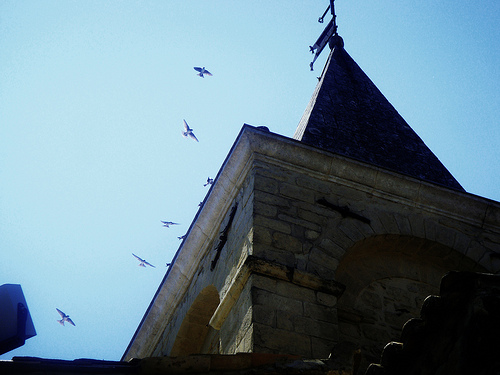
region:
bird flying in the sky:
[50, 304, 82, 334]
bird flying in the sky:
[129, 245, 161, 275]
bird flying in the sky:
[154, 213, 186, 230]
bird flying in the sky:
[175, 117, 204, 147]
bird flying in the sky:
[191, 58, 216, 83]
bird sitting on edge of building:
[204, 171, 221, 192]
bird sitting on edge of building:
[194, 200, 206, 208]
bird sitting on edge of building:
[176, 233, 189, 243]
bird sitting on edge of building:
[163, 261, 178, 268]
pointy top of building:
[141, 11, 481, 360]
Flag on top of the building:
[307, 2, 359, 79]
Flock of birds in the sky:
[54, 64, 220, 329]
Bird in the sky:
[192, 63, 212, 81]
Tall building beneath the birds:
[119, 3, 497, 372]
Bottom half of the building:
[119, 122, 497, 374]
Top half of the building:
[290, 0, 472, 192]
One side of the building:
[251, 127, 498, 372]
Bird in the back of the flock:
[53, 306, 77, 329]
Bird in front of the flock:
[192, 60, 214, 86]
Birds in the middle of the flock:
[130, 118, 217, 270]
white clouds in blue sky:
[19, 11, 73, 51]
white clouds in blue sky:
[22, 74, 86, 126]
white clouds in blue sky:
[10, 140, 68, 180]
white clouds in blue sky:
[25, 198, 64, 228]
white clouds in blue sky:
[105, 35, 133, 75]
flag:
[305, 2, 350, 58]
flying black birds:
[180, 55, 205, 101]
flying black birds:
[175, 107, 196, 139]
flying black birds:
[42, 295, 87, 330]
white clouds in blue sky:
[389, 19, 474, 105]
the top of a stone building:
[11, 5, 498, 370]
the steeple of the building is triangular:
[288, 4, 468, 198]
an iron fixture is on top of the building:
[301, 0, 353, 74]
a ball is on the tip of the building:
[323, 31, 348, 53]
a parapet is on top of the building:
[119, 120, 499, 360]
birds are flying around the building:
[42, 60, 221, 343]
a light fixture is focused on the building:
[6, 270, 41, 357]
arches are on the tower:
[163, 203, 494, 370]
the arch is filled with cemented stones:
[340, 266, 445, 362]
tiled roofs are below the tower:
[6, 266, 498, 373]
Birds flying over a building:
[39, 51, 225, 348]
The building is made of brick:
[206, 151, 341, 363]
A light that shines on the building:
[1, 273, 43, 333]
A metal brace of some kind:
[318, 185, 375, 232]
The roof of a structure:
[392, 255, 477, 372]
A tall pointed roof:
[265, 0, 476, 195]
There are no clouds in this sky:
[3, 0, 485, 217]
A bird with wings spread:
[171, 114, 206, 151]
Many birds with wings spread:
[64, 52, 217, 334]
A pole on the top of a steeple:
[311, 2, 343, 58]